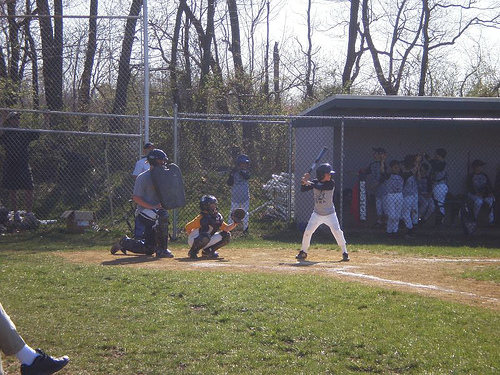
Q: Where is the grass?
A: On the ground.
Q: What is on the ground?
A: Grass.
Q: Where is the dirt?
A: On the ground.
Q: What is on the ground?
A: Dirt.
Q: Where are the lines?
A: On the ground.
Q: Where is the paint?
A: On the ground.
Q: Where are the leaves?
A: On the plants.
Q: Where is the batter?
A: At homebase.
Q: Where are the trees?
A: Behind the field.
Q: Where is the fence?
A: Before the trees.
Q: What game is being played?
A: Baseball.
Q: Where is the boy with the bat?
A: Home plate.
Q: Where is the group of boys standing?
A: Dugout.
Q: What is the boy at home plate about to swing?
A: The bat.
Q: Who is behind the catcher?
A: Umpire.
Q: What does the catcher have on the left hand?
A: Glove.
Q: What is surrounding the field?
A: Fence.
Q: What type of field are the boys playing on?
A: Baseball field.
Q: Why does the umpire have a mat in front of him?
A: Protection.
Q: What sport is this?
A: Baseball.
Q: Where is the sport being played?
A: Baseball field.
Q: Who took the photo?
A: Parent.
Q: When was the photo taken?
A: Afternoon.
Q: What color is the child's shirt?
A: Grey.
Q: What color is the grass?
A: Green.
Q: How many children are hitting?
A: One.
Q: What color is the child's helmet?
A: Navy.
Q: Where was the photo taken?
A: At a ballgame.